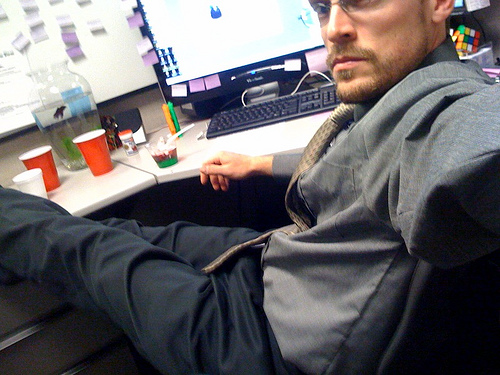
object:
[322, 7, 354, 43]
nose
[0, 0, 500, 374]
man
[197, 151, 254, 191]
hand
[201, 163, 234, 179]
thumb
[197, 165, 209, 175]
nail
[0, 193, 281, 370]
pants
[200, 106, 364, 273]
tie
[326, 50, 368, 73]
mouth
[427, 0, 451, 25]
ear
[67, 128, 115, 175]
cup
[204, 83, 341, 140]
keyboard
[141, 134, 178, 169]
parfait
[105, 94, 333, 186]
desk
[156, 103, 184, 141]
highlighters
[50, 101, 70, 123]
fish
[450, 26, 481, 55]
cube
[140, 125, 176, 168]
food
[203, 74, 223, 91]
post it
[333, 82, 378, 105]
beard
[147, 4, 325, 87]
monitor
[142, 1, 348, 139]
desktop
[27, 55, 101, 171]
bowl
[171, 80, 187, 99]
note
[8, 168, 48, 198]
cup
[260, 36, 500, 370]
suit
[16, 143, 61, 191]
cups